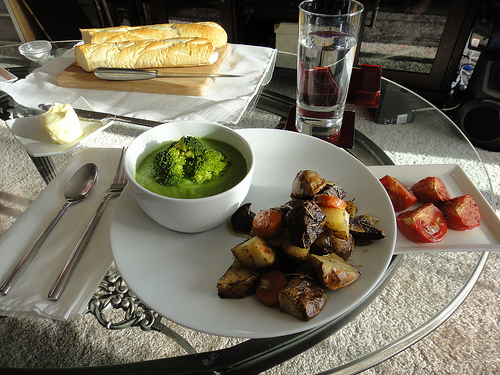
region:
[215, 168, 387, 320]
serving of beef stew on plate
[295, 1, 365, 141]
tall glass of drinking water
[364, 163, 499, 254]
square side plate of grilled tomatoes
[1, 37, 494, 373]
round glass topped table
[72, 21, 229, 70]
portion of bread baguette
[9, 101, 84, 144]
chunk of butter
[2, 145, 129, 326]
napkin with fork and spoon on it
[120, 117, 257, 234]
soup cup with broccoli in it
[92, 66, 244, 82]
knife sitting next to bread on breadboard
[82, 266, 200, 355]
portion of ornate metal table base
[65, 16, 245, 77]
loaf of french bread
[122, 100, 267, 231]
bowl of soup with broccoli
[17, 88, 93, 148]
pat of butter on dish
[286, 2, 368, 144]
tall glass of water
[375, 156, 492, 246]
dish of roasted tomatoes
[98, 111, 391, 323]
food on round white plate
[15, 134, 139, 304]
silverware on a napkin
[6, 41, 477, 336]
dishes on a glass tabletop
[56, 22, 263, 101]
knife and bread on cutting board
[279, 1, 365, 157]
glass on red coaster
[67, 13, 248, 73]
fresh baked bread sticks.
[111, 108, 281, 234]
Broccoli soup in a bowl.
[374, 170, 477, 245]
Tomato slices on a plate.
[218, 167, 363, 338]
meat and vegetable mixture.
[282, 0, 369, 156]
Glass of water on a table.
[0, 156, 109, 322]
silverware on a napkin.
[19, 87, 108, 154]
food item on a plate.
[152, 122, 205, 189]
Broccoli on a soup.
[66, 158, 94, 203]
top of a spoon.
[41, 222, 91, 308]
handle on a fork.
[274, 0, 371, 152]
glass of water on table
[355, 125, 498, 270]
baked tomatoes on plate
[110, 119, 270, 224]
broccoli soup in bowl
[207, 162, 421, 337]
baked vegetables on plate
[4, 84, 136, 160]
butter on plate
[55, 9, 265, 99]
two french loaves on cutting board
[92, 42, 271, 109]
bread knife on board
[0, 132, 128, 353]
spoon and fork on napkin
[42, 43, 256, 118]
cutting board on table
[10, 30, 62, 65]
small container on table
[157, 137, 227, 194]
broccoli on top of soup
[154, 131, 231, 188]
broccoli in a bowl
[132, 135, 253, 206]
green soup in a bowl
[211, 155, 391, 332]
fried potatoes on a plate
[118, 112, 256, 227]
round white bowl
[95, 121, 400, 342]
large round white plate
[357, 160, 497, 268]
fried red tomatoes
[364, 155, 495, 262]
tomatoes on a plate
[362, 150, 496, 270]
a square white plate with a white rim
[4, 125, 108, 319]
a very long shiny spoon